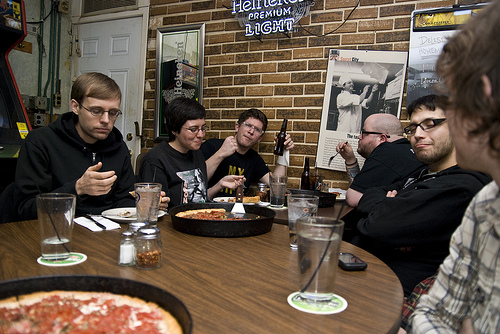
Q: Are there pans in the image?
A: Yes, there is a pan.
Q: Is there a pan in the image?
A: Yes, there is a pan.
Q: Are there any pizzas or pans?
A: Yes, there is a pan.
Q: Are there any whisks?
A: No, there are no whisks.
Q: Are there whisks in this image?
A: No, there are no whisks.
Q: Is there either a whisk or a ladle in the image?
A: No, there are no whisks or ladles.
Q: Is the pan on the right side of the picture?
A: No, the pan is on the left of the image.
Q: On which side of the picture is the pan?
A: The pan is on the left of the image.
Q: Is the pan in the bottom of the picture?
A: Yes, the pan is in the bottom of the image.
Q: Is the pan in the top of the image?
A: No, the pan is in the bottom of the image.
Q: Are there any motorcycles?
A: No, there are no motorcycles.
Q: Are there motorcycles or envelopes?
A: No, there are no motorcycles or envelopes.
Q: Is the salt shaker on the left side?
A: Yes, the salt shaker is on the left of the image.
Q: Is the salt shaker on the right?
A: No, the salt shaker is on the left of the image.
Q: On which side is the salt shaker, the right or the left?
A: The salt shaker is on the left of the image.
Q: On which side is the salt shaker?
A: The salt shaker is on the left of the image.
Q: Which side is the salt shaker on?
A: The salt shaker is on the left of the image.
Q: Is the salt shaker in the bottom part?
A: Yes, the salt shaker is in the bottom of the image.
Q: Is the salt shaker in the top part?
A: No, the salt shaker is in the bottom of the image.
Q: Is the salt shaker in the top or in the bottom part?
A: The salt shaker is in the bottom of the image.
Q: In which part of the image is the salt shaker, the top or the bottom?
A: The salt shaker is in the bottom of the image.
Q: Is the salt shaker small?
A: Yes, the salt shaker is small.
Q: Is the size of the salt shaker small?
A: Yes, the salt shaker is small.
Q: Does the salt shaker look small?
A: Yes, the salt shaker is small.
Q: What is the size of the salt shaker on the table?
A: The salt shaker is small.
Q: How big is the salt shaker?
A: The salt shaker is small.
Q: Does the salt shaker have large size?
A: No, the salt shaker is small.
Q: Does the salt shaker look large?
A: No, the salt shaker is small.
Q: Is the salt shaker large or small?
A: The salt shaker is small.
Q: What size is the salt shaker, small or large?
A: The salt shaker is small.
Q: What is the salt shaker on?
A: The salt shaker is on the table.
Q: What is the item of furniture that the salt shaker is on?
A: The piece of furniture is a table.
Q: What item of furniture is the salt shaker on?
A: The salt shaker is on the table.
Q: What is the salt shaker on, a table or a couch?
A: The salt shaker is on a table.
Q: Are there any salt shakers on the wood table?
A: Yes, there is a salt shaker on the table.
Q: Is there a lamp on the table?
A: No, there is a salt shaker on the table.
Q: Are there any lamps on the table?
A: No, there is a salt shaker on the table.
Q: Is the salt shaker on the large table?
A: Yes, the salt shaker is on the table.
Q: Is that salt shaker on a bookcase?
A: No, the salt shaker is on the table.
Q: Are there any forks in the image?
A: Yes, there is a fork.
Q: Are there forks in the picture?
A: Yes, there is a fork.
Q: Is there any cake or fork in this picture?
A: Yes, there is a fork.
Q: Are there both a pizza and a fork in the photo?
A: Yes, there are both a fork and a pizza.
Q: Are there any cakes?
A: No, there are no cakes.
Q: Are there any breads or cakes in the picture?
A: No, there are no cakes or breads.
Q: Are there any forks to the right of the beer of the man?
A: Yes, there is a fork to the right of the beer.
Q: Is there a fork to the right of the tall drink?
A: Yes, there is a fork to the right of the beer.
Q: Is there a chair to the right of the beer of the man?
A: No, there is a fork to the right of the beer.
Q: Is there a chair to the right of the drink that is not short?
A: No, there is a fork to the right of the beer.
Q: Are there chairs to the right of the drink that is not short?
A: No, there is a fork to the right of the beer.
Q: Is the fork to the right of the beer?
A: Yes, the fork is to the right of the beer.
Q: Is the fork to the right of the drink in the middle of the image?
A: Yes, the fork is to the right of the beer.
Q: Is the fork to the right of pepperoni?
A: No, the fork is to the right of the beer.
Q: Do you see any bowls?
A: No, there are no bowls.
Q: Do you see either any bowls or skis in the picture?
A: No, there are no bowls or skis.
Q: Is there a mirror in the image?
A: Yes, there is a mirror.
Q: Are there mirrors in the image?
A: Yes, there is a mirror.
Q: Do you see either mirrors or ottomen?
A: Yes, there is a mirror.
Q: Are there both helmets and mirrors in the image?
A: No, there is a mirror but no helmets.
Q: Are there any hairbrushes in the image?
A: No, there are no hairbrushes.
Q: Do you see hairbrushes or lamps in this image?
A: No, there are no hairbrushes or lamps.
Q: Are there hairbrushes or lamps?
A: No, there are no hairbrushes or lamps.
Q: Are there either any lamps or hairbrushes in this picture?
A: No, there are no hairbrushes or lamps.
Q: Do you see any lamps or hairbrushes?
A: No, there are no hairbrushes or lamps.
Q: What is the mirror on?
A: The mirror is on the wall.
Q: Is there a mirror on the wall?
A: Yes, there is a mirror on the wall.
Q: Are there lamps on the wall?
A: No, there is a mirror on the wall.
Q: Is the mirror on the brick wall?
A: Yes, the mirror is on the wall.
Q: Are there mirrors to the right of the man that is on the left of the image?
A: Yes, there is a mirror to the right of the man.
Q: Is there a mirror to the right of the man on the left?
A: Yes, there is a mirror to the right of the man.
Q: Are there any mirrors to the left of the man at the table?
A: No, the mirror is to the right of the man.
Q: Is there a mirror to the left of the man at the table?
A: No, the mirror is to the right of the man.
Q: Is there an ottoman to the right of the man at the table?
A: No, there is a mirror to the right of the man.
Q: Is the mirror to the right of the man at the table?
A: Yes, the mirror is to the right of the man.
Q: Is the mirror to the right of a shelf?
A: No, the mirror is to the right of the man.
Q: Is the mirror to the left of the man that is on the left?
A: No, the mirror is to the right of the man.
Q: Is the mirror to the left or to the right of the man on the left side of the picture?
A: The mirror is to the right of the man.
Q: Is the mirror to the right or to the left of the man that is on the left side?
A: The mirror is to the right of the man.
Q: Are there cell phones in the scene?
A: Yes, there is a cell phone.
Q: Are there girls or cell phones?
A: Yes, there is a cell phone.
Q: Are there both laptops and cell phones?
A: No, there is a cell phone but no laptops.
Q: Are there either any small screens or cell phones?
A: Yes, there is a small cell phone.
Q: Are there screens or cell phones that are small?
A: Yes, the cell phone is small.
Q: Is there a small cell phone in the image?
A: Yes, there is a small cell phone.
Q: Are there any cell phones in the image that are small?
A: Yes, there is a cell phone that is small.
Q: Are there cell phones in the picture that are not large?
A: Yes, there is a small cell phone.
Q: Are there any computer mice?
A: No, there are no computer mice.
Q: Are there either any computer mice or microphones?
A: No, there are no computer mice or microphones.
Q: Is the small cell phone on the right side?
A: Yes, the cellphone is on the right of the image.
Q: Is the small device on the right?
A: Yes, the cellphone is on the right of the image.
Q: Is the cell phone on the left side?
A: No, the cell phone is on the right of the image.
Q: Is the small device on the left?
A: No, the cell phone is on the right of the image.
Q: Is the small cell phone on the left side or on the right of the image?
A: The cellphone is on the right of the image.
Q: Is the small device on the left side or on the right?
A: The cellphone is on the right of the image.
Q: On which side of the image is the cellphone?
A: The cellphone is on the right of the image.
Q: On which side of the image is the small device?
A: The cellphone is on the right of the image.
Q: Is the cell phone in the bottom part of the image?
A: Yes, the cell phone is in the bottom of the image.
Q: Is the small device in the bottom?
A: Yes, the cell phone is in the bottom of the image.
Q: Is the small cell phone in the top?
A: No, the cellphone is in the bottom of the image.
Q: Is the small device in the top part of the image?
A: No, the cellphone is in the bottom of the image.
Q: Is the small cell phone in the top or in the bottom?
A: The mobile phone is in the bottom of the image.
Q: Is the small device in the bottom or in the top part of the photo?
A: The mobile phone is in the bottom of the image.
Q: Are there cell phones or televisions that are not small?
A: No, there is a cell phone but it is small.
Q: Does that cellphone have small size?
A: Yes, the cellphone is small.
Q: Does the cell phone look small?
A: Yes, the cell phone is small.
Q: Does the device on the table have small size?
A: Yes, the cell phone is small.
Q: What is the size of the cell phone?
A: The cell phone is small.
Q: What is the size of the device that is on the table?
A: The cell phone is small.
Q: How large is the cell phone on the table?
A: The cellphone is small.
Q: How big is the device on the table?
A: The cellphone is small.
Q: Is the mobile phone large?
A: No, the mobile phone is small.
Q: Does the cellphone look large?
A: No, the cellphone is small.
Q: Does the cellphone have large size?
A: No, the cellphone is small.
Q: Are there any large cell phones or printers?
A: No, there is a cell phone but it is small.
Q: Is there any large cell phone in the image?
A: No, there is a cell phone but it is small.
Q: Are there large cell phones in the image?
A: No, there is a cell phone but it is small.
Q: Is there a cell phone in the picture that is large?
A: No, there is a cell phone but it is small.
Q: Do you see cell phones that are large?
A: No, there is a cell phone but it is small.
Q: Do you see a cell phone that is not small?
A: No, there is a cell phone but it is small.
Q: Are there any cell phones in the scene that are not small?
A: No, there is a cell phone but it is small.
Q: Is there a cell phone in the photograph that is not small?
A: No, there is a cell phone but it is small.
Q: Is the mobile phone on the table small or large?
A: The mobile phone is small.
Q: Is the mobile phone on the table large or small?
A: The mobile phone is small.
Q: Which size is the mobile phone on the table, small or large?
A: The mobile phone is small.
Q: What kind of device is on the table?
A: The device is a cell phone.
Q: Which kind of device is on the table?
A: The device is a cell phone.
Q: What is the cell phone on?
A: The cell phone is on the table.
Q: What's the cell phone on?
A: The cell phone is on the table.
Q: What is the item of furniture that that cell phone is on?
A: The piece of furniture is a table.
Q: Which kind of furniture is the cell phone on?
A: The cell phone is on the table.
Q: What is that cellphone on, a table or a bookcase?
A: The cellphone is on a table.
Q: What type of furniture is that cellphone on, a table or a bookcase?
A: The cellphone is on a table.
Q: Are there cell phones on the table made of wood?
A: Yes, there is a cell phone on the table.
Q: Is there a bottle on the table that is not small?
A: No, there is a cell phone on the table.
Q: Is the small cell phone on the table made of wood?
A: Yes, the cellphone is on the table.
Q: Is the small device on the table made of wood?
A: Yes, the cellphone is on the table.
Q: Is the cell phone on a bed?
A: No, the cell phone is on the table.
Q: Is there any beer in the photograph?
A: Yes, there is beer.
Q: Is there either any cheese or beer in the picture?
A: Yes, there is beer.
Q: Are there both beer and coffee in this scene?
A: No, there is beer but no coffee.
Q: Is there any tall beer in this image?
A: Yes, there is tall beer.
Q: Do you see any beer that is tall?
A: Yes, there is beer that is tall.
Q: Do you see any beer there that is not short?
A: Yes, there is tall beer.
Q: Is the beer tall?
A: Yes, the beer is tall.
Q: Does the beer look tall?
A: Yes, the beer is tall.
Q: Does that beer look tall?
A: Yes, the beer is tall.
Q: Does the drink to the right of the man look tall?
A: Yes, the beer is tall.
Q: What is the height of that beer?
A: The beer is tall.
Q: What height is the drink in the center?
A: The beer is tall.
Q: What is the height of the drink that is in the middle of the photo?
A: The beer is tall.